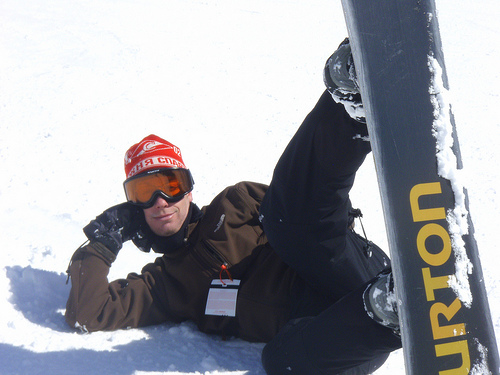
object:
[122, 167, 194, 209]
goggles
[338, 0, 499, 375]
board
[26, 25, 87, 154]
snow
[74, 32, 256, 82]
snow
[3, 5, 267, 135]
snow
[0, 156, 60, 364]
snow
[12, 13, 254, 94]
snow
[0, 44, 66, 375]
snow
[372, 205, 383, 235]
snow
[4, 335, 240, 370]
snow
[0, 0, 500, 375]
snow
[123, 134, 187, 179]
beanie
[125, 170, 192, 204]
lens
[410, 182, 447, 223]
letter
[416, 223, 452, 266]
letter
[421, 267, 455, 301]
letter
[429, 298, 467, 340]
letter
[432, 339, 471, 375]
letter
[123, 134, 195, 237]
head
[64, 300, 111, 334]
elbow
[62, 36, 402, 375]
man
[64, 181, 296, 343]
jacket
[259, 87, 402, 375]
pants